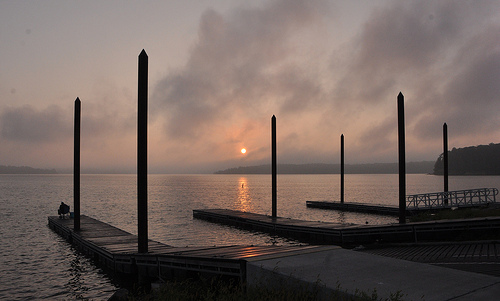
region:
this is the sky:
[26, 16, 127, 70]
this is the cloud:
[179, 52, 289, 113]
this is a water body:
[165, 165, 200, 202]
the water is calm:
[10, 217, 41, 259]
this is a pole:
[132, 44, 161, 242]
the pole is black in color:
[132, 48, 165, 200]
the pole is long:
[126, 58, 161, 160]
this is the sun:
[232, 144, 248, 157]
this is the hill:
[456, 142, 498, 168]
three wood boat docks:
[34, 179, 409, 265]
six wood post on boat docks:
[47, 89, 460, 257]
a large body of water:
[45, 142, 380, 252]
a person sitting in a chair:
[40, 190, 84, 225]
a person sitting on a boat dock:
[45, 182, 82, 234]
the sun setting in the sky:
[207, 118, 267, 188]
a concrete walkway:
[248, 248, 446, 290]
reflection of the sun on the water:
[206, 169, 263, 214]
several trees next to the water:
[427, 137, 488, 182]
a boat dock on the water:
[180, 184, 354, 238]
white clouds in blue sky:
[190, 61, 237, 106]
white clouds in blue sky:
[224, 21, 318, 116]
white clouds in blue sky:
[315, 8, 350, 52]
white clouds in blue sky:
[57, 51, 67, 72]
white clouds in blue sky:
[28, 32, 63, 74]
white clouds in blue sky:
[10, 108, 45, 159]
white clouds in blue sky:
[148, 79, 183, 149]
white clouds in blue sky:
[287, 56, 338, 118]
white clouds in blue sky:
[350, 26, 382, 71]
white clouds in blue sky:
[172, 25, 220, 66]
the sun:
[224, 132, 263, 168]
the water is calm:
[161, 172, 232, 214]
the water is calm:
[154, 155, 214, 189]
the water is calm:
[151, 165, 241, 197]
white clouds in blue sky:
[15, 3, 67, 53]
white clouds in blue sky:
[192, 55, 247, 87]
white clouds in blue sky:
[275, 5, 356, 67]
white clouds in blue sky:
[350, 13, 415, 63]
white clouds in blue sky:
[187, 42, 239, 77]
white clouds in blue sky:
[198, 99, 243, 133]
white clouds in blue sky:
[50, 15, 115, 39]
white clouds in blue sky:
[27, 28, 127, 65]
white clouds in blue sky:
[18, 108, 55, 148]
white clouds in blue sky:
[172, 59, 232, 136]